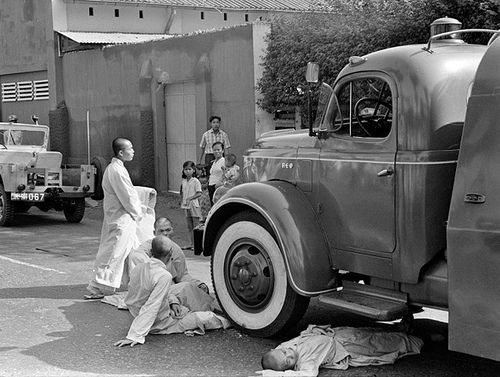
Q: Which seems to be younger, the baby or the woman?
A: The baby is younger than the woman.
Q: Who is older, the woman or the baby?
A: The woman is older than the baby.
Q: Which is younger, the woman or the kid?
A: The kid is younger than the woman.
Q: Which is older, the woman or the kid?
A: The woman is older than the kid.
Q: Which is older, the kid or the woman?
A: The woman is older than the kid.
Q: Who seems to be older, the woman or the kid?
A: The woman is older than the kid.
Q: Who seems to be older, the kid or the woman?
A: The woman is older than the kid.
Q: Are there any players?
A: No, there are no players.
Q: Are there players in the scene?
A: No, there are no players.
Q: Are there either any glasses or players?
A: No, there are no players or glasses.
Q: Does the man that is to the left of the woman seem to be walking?
A: Yes, the man is walking.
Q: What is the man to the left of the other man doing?
A: The man is walking.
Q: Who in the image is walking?
A: The man is walking.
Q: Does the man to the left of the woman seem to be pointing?
A: No, the man is walking.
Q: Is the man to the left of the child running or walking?
A: The man is walking.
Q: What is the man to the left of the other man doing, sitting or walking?
A: The man is walking.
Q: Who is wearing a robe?
A: The man is wearing a robe.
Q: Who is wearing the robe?
A: The man is wearing a robe.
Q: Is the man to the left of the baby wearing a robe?
A: Yes, the man is wearing a robe.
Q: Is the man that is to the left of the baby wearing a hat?
A: No, the man is wearing a robe.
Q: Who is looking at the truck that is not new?
A: The man is looking at the truck.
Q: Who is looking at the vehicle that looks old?
A: The man is looking at the truck.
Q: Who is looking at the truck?
A: The man is looking at the truck.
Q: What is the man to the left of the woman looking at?
A: The man is looking at the truck.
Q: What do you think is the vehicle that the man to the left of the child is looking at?
A: The vehicle is a truck.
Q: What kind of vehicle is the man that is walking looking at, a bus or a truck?
A: The man is looking at a truck.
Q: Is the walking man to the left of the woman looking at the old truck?
A: Yes, the man is looking at the truck.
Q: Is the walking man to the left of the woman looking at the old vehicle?
A: Yes, the man is looking at the truck.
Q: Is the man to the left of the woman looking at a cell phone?
A: No, the man is looking at the truck.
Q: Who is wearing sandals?
A: The man is wearing sandals.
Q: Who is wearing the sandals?
A: The man is wearing sandals.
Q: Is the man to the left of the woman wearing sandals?
A: Yes, the man is wearing sandals.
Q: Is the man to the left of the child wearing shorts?
A: No, the man is wearing sandals.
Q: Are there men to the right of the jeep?
A: Yes, there is a man to the right of the jeep.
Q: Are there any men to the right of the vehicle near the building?
A: Yes, there is a man to the right of the jeep.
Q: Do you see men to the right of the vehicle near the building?
A: Yes, there is a man to the right of the jeep.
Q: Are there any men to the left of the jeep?
A: No, the man is to the right of the jeep.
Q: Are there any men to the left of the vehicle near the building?
A: No, the man is to the right of the jeep.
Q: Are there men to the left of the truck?
A: Yes, there is a man to the left of the truck.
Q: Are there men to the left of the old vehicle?
A: Yes, there is a man to the left of the truck.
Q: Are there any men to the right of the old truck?
A: No, the man is to the left of the truck.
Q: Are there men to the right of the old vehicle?
A: No, the man is to the left of the truck.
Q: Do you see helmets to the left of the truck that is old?
A: No, there is a man to the left of the truck.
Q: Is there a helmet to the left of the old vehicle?
A: No, there is a man to the left of the truck.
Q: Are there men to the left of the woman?
A: Yes, there is a man to the left of the woman.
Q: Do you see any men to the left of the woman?
A: Yes, there is a man to the left of the woman.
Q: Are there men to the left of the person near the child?
A: Yes, there is a man to the left of the woman.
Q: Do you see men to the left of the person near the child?
A: Yes, there is a man to the left of the woman.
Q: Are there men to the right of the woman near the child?
A: No, the man is to the left of the woman.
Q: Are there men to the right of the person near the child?
A: No, the man is to the left of the woman.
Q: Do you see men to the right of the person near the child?
A: No, the man is to the left of the woman.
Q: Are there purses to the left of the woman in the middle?
A: No, there is a man to the left of the woman.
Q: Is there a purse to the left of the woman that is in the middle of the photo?
A: No, there is a man to the left of the woman.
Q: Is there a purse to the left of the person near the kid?
A: No, there is a man to the left of the woman.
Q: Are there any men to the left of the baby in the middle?
A: Yes, there is a man to the left of the baby.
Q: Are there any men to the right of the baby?
A: No, the man is to the left of the baby.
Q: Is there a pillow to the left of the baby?
A: No, there is a man to the left of the baby.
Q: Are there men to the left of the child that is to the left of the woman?
A: Yes, there is a man to the left of the child.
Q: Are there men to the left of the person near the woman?
A: Yes, there is a man to the left of the child.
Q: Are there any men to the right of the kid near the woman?
A: No, the man is to the left of the child.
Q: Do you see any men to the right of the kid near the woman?
A: No, the man is to the left of the child.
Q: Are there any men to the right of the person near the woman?
A: No, the man is to the left of the child.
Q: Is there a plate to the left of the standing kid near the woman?
A: No, there is a man to the left of the kid.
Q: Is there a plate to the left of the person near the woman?
A: No, there is a man to the left of the kid.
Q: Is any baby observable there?
A: Yes, there is a baby.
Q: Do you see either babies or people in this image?
A: Yes, there is a baby.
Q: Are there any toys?
A: No, there are no toys.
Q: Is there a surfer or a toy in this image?
A: No, there are no toys or surfers.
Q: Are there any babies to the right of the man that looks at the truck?
A: Yes, there is a baby to the right of the man.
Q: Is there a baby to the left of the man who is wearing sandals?
A: No, the baby is to the right of the man.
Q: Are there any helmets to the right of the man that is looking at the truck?
A: No, there is a baby to the right of the man.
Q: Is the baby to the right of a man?
A: Yes, the baby is to the right of a man.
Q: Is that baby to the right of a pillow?
A: No, the baby is to the right of a man.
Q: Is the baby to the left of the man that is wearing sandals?
A: No, the baby is to the right of the man.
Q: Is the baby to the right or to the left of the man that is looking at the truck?
A: The baby is to the right of the man.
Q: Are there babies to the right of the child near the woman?
A: Yes, there is a baby to the right of the child.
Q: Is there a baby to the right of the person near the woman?
A: Yes, there is a baby to the right of the child.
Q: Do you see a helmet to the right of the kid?
A: No, there is a baby to the right of the kid.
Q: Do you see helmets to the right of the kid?
A: No, there is a baby to the right of the kid.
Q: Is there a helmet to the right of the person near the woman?
A: No, there is a baby to the right of the kid.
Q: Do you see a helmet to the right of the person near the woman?
A: No, there is a baby to the right of the kid.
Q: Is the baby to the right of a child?
A: Yes, the baby is to the right of a child.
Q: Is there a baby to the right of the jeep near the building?
A: Yes, there is a baby to the right of the jeep.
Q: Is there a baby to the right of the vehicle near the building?
A: Yes, there is a baby to the right of the jeep.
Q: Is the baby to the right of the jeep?
A: Yes, the baby is to the right of the jeep.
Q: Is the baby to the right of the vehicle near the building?
A: Yes, the baby is to the right of the jeep.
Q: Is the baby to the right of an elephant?
A: No, the baby is to the right of the jeep.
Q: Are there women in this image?
A: Yes, there is a woman.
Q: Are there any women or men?
A: Yes, there is a woman.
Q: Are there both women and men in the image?
A: Yes, there are both a woman and a man.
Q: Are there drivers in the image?
A: No, there are no drivers.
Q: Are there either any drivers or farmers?
A: No, there are no drivers or farmers.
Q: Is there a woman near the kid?
A: Yes, there is a woman near the kid.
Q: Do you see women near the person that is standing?
A: Yes, there is a woman near the kid.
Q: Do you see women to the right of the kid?
A: Yes, there is a woman to the right of the kid.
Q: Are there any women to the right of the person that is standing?
A: Yes, there is a woman to the right of the kid.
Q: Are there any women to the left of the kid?
A: No, the woman is to the right of the kid.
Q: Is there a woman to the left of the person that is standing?
A: No, the woman is to the right of the kid.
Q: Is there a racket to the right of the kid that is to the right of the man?
A: No, there is a woman to the right of the kid.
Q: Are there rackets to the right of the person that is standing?
A: No, there is a woman to the right of the kid.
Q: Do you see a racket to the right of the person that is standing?
A: No, there is a woman to the right of the kid.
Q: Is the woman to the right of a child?
A: Yes, the woman is to the right of a child.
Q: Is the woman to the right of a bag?
A: No, the woman is to the right of a child.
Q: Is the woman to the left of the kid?
A: No, the woman is to the right of the kid.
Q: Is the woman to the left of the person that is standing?
A: No, the woman is to the right of the kid.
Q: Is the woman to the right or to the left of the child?
A: The woman is to the right of the child.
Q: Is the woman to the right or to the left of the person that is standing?
A: The woman is to the right of the child.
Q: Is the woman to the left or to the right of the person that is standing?
A: The woman is to the right of the child.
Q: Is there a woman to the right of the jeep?
A: Yes, there is a woman to the right of the jeep.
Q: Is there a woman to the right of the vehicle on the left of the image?
A: Yes, there is a woman to the right of the jeep.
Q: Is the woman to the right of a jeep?
A: Yes, the woman is to the right of a jeep.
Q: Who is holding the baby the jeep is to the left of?
A: The woman is holding the baby.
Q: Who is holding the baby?
A: The woman is holding the baby.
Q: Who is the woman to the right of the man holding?
A: The woman is holding the baby.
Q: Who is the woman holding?
A: The woman is holding the baby.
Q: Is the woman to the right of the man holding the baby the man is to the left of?
A: Yes, the woman is holding the baby.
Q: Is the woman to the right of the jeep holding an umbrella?
A: No, the woman is holding the baby.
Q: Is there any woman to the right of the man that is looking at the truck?
A: Yes, there is a woman to the right of the man.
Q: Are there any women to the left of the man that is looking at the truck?
A: No, the woman is to the right of the man.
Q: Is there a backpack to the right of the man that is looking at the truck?
A: No, there is a woman to the right of the man.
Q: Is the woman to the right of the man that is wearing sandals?
A: Yes, the woman is to the right of the man.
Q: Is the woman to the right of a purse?
A: No, the woman is to the right of the man.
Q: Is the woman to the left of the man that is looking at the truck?
A: No, the woman is to the right of the man.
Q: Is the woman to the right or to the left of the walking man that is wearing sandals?
A: The woman is to the right of the man.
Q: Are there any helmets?
A: No, there are no helmets.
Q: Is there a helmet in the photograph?
A: No, there are no helmets.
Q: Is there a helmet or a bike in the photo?
A: No, there are no helmets or bikes.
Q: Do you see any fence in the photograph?
A: No, there are no fences.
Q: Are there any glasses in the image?
A: No, there are no glasses.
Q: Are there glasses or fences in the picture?
A: No, there are no glasses or fences.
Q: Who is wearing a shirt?
A: The man is wearing a shirt.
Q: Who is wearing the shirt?
A: The man is wearing a shirt.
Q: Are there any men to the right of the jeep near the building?
A: Yes, there is a man to the right of the jeep.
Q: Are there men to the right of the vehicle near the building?
A: Yes, there is a man to the right of the jeep.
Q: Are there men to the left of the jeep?
A: No, the man is to the right of the jeep.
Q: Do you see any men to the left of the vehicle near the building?
A: No, the man is to the right of the jeep.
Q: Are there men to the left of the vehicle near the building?
A: No, the man is to the right of the jeep.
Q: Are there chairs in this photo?
A: No, there are no chairs.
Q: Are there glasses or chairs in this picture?
A: No, there are no chairs or glasses.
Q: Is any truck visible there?
A: Yes, there is a truck.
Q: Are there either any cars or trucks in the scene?
A: Yes, there is a truck.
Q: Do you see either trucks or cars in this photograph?
A: Yes, there is a truck.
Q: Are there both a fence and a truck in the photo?
A: No, there is a truck but no fences.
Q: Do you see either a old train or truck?
A: Yes, there is an old truck.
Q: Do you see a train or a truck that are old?
A: Yes, the truck is old.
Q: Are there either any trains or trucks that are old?
A: Yes, the truck is old.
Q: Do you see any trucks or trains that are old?
A: Yes, the truck is old.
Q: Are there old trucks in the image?
A: Yes, there is an old truck.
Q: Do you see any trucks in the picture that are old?
A: Yes, there is a truck that is old.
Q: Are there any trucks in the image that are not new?
A: Yes, there is a old truck.